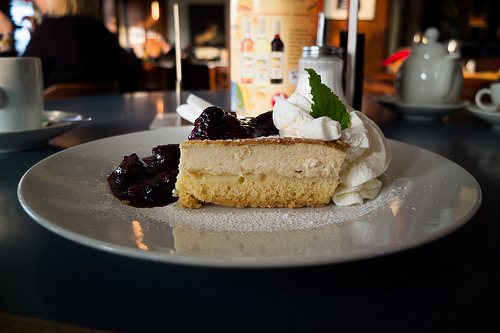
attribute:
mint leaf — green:
[305, 64, 352, 132]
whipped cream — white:
[277, 84, 391, 205]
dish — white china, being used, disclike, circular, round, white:
[17, 123, 484, 270]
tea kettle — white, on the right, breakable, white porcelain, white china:
[390, 27, 467, 114]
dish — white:
[373, 95, 468, 122]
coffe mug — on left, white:
[0, 55, 47, 133]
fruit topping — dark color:
[111, 109, 284, 209]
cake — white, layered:
[178, 124, 351, 213]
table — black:
[3, 84, 490, 329]